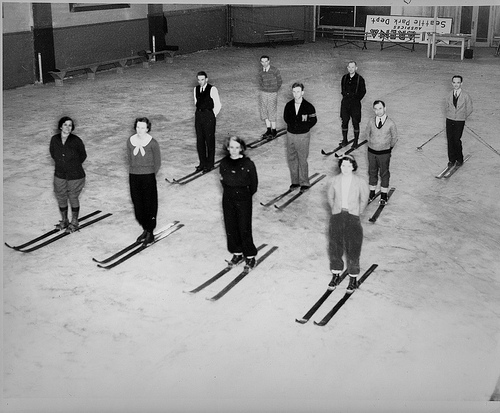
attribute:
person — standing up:
[250, 52, 283, 144]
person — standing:
[213, 129, 265, 271]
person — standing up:
[291, 141, 414, 285]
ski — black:
[297, 156, 415, 337]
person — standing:
[174, 66, 219, 161]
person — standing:
[117, 117, 169, 231]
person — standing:
[336, 82, 463, 222]